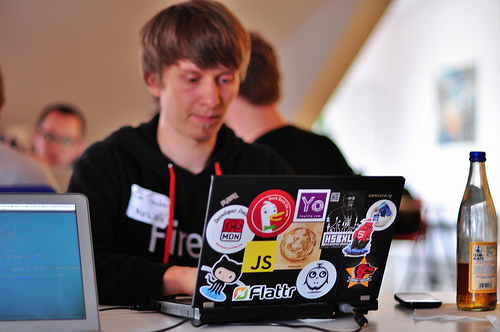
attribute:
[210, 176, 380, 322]
laptop — black, computer, silver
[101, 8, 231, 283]
man — sitting, using, typing, looking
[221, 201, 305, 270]
stickers — many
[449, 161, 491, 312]
bottle — glass, full, soda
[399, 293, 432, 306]
phone — black, up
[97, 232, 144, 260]
hoodie — black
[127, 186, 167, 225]
tag — white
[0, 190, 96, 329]
monitor — silver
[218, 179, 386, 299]
screen — blue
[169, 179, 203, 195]
shirt — black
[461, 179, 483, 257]
drink — half gone, glass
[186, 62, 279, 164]
people — background, blurry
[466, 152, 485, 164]
top — blue